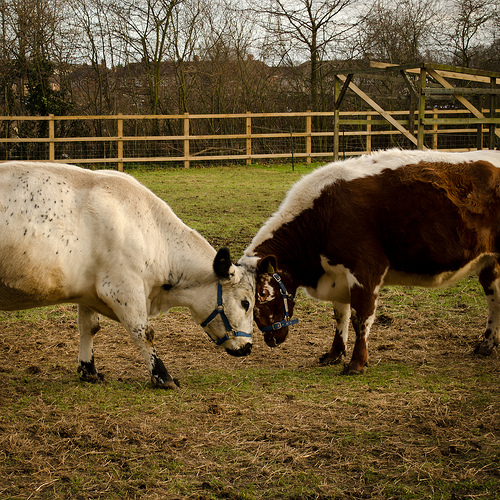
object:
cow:
[234, 146, 499, 378]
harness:
[197, 282, 255, 349]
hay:
[0, 312, 68, 373]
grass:
[3, 402, 500, 498]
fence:
[170, 108, 252, 171]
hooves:
[74, 359, 106, 387]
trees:
[260, 1, 371, 163]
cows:
[0, 158, 259, 390]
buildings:
[6, 56, 68, 113]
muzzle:
[250, 264, 298, 336]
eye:
[254, 289, 268, 300]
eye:
[240, 298, 250, 312]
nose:
[264, 336, 277, 350]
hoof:
[340, 361, 373, 375]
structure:
[332, 51, 499, 156]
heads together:
[198, 243, 298, 361]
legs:
[97, 282, 179, 390]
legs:
[341, 265, 379, 376]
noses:
[242, 342, 254, 354]